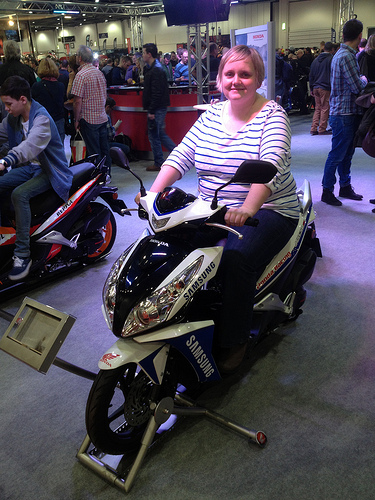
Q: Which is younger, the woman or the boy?
A: The boy is younger than the woman.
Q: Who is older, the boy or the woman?
A: The woman is older than the boy.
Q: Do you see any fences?
A: No, there are no fences.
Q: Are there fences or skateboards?
A: No, there are no fences or skateboards.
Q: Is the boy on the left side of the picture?
A: Yes, the boy is on the left of the image.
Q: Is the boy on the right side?
A: No, the boy is on the left of the image.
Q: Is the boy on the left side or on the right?
A: The boy is on the left of the image.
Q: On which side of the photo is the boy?
A: The boy is on the left of the image.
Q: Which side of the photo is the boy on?
A: The boy is on the left of the image.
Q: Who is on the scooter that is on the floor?
A: The boy is on the scooter.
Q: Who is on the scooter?
A: The boy is on the scooter.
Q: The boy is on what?
A: The boy is on the scooter.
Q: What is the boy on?
A: The boy is on the scooter.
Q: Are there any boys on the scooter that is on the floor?
A: Yes, there is a boy on the scooter.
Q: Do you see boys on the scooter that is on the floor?
A: Yes, there is a boy on the scooter.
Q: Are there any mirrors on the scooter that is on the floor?
A: No, there is a boy on the scooter.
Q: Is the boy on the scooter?
A: Yes, the boy is on the scooter.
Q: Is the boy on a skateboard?
A: No, the boy is on the scooter.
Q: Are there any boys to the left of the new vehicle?
A: Yes, there is a boy to the left of the vehicle.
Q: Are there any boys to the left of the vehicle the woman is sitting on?
A: Yes, there is a boy to the left of the vehicle.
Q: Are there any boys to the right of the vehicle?
A: No, the boy is to the left of the vehicle.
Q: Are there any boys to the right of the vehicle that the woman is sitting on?
A: No, the boy is to the left of the vehicle.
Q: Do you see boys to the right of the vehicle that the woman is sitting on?
A: No, the boy is to the left of the vehicle.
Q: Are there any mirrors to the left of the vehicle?
A: No, there is a boy to the left of the vehicle.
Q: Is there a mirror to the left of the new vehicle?
A: No, there is a boy to the left of the vehicle.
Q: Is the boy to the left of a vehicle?
A: Yes, the boy is to the left of a vehicle.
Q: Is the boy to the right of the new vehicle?
A: No, the boy is to the left of the vehicle.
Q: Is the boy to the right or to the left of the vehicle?
A: The boy is to the left of the vehicle.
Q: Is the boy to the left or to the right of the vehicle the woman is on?
A: The boy is to the left of the vehicle.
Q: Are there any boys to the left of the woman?
A: Yes, there is a boy to the left of the woman.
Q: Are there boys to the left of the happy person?
A: Yes, there is a boy to the left of the woman.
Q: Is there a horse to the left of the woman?
A: No, there is a boy to the left of the woman.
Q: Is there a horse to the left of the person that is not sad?
A: No, there is a boy to the left of the woman.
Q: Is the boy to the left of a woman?
A: Yes, the boy is to the left of a woman.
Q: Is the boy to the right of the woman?
A: No, the boy is to the left of the woman.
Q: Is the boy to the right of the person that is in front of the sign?
A: No, the boy is to the left of the woman.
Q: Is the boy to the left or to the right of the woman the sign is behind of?
A: The boy is to the left of the woman.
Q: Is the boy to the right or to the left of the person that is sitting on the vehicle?
A: The boy is to the left of the woman.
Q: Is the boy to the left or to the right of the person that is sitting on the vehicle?
A: The boy is to the left of the woman.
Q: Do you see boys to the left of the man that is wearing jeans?
A: Yes, there is a boy to the left of the man.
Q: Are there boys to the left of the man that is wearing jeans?
A: Yes, there is a boy to the left of the man.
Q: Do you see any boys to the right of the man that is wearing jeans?
A: No, the boy is to the left of the man.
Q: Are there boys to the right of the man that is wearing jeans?
A: No, the boy is to the left of the man.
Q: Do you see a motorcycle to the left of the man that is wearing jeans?
A: No, there is a boy to the left of the man.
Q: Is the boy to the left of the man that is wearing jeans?
A: Yes, the boy is to the left of the man.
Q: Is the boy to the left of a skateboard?
A: No, the boy is to the left of the man.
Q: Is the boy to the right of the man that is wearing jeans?
A: No, the boy is to the left of the man.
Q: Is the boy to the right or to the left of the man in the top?
A: The boy is to the left of the man.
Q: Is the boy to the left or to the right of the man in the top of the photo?
A: The boy is to the left of the man.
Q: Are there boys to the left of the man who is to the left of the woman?
A: Yes, there is a boy to the left of the man.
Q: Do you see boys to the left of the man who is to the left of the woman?
A: Yes, there is a boy to the left of the man.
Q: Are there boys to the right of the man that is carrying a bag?
A: No, the boy is to the left of the man.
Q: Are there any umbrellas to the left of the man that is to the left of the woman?
A: No, there is a boy to the left of the man.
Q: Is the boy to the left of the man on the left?
A: Yes, the boy is to the left of the man.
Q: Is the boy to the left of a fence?
A: No, the boy is to the left of the man.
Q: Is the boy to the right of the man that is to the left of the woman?
A: No, the boy is to the left of the man.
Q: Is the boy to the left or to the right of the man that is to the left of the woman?
A: The boy is to the left of the man.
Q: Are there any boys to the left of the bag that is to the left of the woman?
A: Yes, there is a boy to the left of the bag.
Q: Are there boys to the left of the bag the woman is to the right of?
A: Yes, there is a boy to the left of the bag.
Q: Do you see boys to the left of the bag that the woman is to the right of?
A: Yes, there is a boy to the left of the bag.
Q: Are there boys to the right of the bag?
A: No, the boy is to the left of the bag.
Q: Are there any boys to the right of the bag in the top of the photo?
A: No, the boy is to the left of the bag.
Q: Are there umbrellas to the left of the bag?
A: No, there is a boy to the left of the bag.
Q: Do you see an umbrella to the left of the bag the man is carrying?
A: No, there is a boy to the left of the bag.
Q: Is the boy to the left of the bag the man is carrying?
A: Yes, the boy is to the left of the bag.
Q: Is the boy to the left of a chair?
A: No, the boy is to the left of the bag.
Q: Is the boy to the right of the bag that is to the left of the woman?
A: No, the boy is to the left of the bag.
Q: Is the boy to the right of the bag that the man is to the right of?
A: No, the boy is to the left of the bag.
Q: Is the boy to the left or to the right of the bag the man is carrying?
A: The boy is to the left of the bag.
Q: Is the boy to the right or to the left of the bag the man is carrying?
A: The boy is to the left of the bag.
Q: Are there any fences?
A: No, there are no fences.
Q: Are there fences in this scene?
A: No, there are no fences.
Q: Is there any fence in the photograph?
A: No, there are no fences.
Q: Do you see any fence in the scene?
A: No, there are no fences.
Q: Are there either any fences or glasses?
A: No, there are no fences or glasses.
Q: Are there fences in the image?
A: No, there are no fences.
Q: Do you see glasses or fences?
A: No, there are no fences or glasses.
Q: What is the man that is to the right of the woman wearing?
A: The man is wearing a shirt.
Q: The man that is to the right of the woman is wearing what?
A: The man is wearing a shirt.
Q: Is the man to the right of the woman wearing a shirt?
A: Yes, the man is wearing a shirt.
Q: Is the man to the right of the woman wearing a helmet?
A: No, the man is wearing a shirt.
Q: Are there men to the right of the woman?
A: Yes, there is a man to the right of the woman.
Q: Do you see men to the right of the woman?
A: Yes, there is a man to the right of the woman.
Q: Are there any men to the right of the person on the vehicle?
A: Yes, there is a man to the right of the woman.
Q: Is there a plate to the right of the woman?
A: No, there is a man to the right of the woman.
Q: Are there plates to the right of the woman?
A: No, there is a man to the right of the woman.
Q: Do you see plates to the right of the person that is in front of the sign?
A: No, there is a man to the right of the woman.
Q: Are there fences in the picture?
A: No, there are no fences.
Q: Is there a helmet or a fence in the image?
A: No, there are no fences or helmets.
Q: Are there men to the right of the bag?
A: Yes, there is a man to the right of the bag.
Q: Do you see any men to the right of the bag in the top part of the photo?
A: Yes, there is a man to the right of the bag.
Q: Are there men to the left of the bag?
A: No, the man is to the right of the bag.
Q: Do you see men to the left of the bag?
A: No, the man is to the right of the bag.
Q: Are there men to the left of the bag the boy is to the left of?
A: No, the man is to the right of the bag.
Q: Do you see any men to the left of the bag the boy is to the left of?
A: No, the man is to the right of the bag.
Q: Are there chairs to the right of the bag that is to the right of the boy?
A: No, there is a man to the right of the bag.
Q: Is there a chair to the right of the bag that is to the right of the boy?
A: No, there is a man to the right of the bag.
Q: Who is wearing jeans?
A: The man is wearing jeans.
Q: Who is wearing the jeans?
A: The man is wearing jeans.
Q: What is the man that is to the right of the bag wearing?
A: The man is wearing jeans.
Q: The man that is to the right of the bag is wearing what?
A: The man is wearing jeans.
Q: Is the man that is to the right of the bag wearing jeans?
A: Yes, the man is wearing jeans.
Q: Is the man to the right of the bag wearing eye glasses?
A: No, the man is wearing jeans.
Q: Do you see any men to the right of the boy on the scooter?
A: Yes, there is a man to the right of the boy.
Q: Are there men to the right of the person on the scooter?
A: Yes, there is a man to the right of the boy.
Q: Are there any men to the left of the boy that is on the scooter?
A: No, the man is to the right of the boy.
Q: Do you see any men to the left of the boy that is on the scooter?
A: No, the man is to the right of the boy.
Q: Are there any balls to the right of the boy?
A: No, there is a man to the right of the boy.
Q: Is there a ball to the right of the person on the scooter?
A: No, there is a man to the right of the boy.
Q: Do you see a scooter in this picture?
A: Yes, there is a scooter.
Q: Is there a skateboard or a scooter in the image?
A: Yes, there is a scooter.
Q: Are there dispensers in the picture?
A: No, there are no dispensers.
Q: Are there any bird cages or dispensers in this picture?
A: No, there are no dispensers or bird cages.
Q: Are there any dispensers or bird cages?
A: No, there are no dispensers or bird cages.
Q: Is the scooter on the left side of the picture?
A: Yes, the scooter is on the left of the image.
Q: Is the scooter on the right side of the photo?
A: No, the scooter is on the left of the image.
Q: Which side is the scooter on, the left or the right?
A: The scooter is on the left of the image.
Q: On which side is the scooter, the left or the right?
A: The scooter is on the left of the image.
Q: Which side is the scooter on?
A: The scooter is on the left of the image.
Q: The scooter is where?
A: The scooter is on the floor.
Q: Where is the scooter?
A: The scooter is on the floor.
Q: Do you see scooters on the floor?
A: Yes, there is a scooter on the floor.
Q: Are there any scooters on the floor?
A: Yes, there is a scooter on the floor.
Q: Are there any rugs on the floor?
A: No, there is a scooter on the floor.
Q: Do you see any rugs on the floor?
A: No, there is a scooter on the floor.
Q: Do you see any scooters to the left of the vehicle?
A: Yes, there is a scooter to the left of the vehicle.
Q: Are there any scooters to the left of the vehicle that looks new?
A: Yes, there is a scooter to the left of the vehicle.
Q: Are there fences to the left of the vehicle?
A: No, there is a scooter to the left of the vehicle.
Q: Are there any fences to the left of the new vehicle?
A: No, there is a scooter to the left of the vehicle.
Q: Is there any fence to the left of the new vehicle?
A: No, there is a scooter to the left of the vehicle.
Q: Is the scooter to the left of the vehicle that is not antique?
A: Yes, the scooter is to the left of the vehicle.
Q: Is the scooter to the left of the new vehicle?
A: Yes, the scooter is to the left of the vehicle.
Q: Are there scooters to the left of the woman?
A: Yes, there is a scooter to the left of the woman.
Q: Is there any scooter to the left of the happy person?
A: Yes, there is a scooter to the left of the woman.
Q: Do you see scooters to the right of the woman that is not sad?
A: No, the scooter is to the left of the woman.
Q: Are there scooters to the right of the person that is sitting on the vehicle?
A: No, the scooter is to the left of the woman.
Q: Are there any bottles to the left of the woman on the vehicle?
A: No, there is a scooter to the left of the woman.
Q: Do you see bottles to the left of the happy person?
A: No, there is a scooter to the left of the woman.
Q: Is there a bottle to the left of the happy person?
A: No, there is a scooter to the left of the woman.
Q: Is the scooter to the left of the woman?
A: Yes, the scooter is to the left of the woman.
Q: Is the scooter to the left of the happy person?
A: Yes, the scooter is to the left of the woman.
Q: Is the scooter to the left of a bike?
A: No, the scooter is to the left of the woman.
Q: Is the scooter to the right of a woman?
A: No, the scooter is to the left of a woman.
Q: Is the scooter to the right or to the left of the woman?
A: The scooter is to the left of the woman.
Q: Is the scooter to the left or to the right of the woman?
A: The scooter is to the left of the woman.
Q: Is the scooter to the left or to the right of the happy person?
A: The scooter is to the left of the woman.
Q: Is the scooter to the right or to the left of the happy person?
A: The scooter is to the left of the woman.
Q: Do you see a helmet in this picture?
A: No, there are no helmets.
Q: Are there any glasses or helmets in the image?
A: No, there are no helmets or glasses.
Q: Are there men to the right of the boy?
A: Yes, there is a man to the right of the boy.